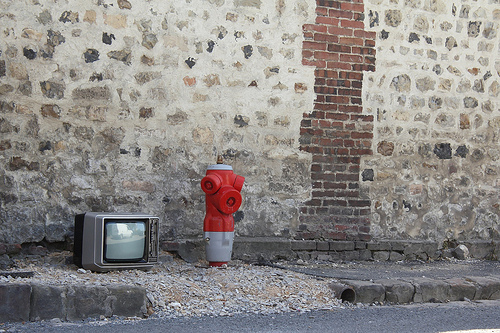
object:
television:
[74, 210, 161, 272]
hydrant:
[198, 164, 245, 268]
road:
[0, 299, 500, 333]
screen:
[104, 219, 149, 261]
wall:
[0, 2, 500, 262]